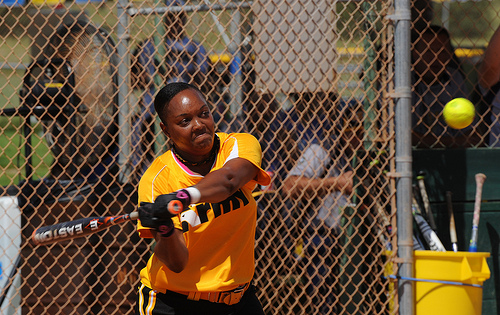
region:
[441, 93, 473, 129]
a small green tennis ball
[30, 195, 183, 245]
a black baseball bat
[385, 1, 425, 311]
a tall gray pole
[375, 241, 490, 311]
a large yellow bucket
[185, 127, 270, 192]
the arm of a girl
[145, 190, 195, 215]
a black glove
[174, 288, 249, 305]
a woman's yellow belt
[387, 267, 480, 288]
a long blue rope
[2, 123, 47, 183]
a section of green grass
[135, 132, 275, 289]
a woman's short sleeve yellow shirt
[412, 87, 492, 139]
The ball is in mid air.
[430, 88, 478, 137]
The ball is chartreuse.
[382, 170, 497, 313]
The bucket is yellow.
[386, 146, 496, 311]
The bucket has bats in it.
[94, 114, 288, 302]
The person is wearing a yellow top.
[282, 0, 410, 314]
The fence is made of wire.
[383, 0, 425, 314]
The fence pole is metal.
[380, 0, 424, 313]
The fence pole is gray.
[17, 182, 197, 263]
The person is swinging a bat.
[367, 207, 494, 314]
The bucket is plastic.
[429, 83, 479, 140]
yellow ball in mid air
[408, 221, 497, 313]
plastic yellow bat bin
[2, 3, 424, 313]
metal chain link fence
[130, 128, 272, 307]
ladies yellow sports tee shirt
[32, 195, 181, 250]
easton aluminum baseball bat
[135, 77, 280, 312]
woman swinging bat at ball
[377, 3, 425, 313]
silver metal fence pole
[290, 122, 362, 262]
casual gray tee shirt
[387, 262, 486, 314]
blue strap for holding bin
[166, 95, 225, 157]
determined face of baseball batter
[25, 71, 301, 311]
woman swinging a baseball bat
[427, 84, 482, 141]
bright yellow ball in the air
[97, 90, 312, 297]
woman wearing a yellow shirt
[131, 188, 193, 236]
black sports gloves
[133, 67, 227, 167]
black hair slicked down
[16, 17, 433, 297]
fence behind a person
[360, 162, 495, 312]
yellow can full of bats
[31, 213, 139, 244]
bat with letters on it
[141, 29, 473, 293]
people watching the game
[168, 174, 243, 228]
black letters on a shirt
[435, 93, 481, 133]
bright yellow softball in air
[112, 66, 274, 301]
woman wearing yellow t-shirt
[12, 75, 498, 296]
woman attempting to hit softball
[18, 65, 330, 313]
woman holding bat with two hands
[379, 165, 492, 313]
bucket full of baseball bats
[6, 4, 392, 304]
rusty meshed fence behind woman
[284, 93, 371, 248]
person wearing light colored t-shirt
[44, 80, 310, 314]
woman wearing black pants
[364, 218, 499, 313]
yellow tall garbage can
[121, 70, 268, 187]
woman with short black hair